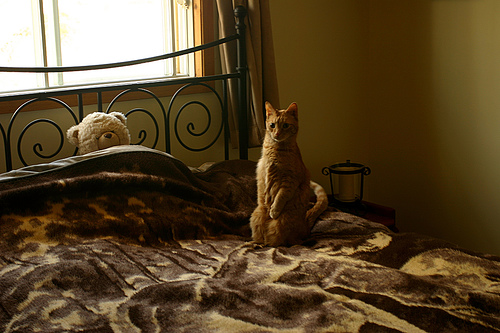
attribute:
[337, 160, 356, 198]
candle — white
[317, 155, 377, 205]
container — wire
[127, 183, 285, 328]
duvet — heavy, brown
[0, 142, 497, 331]
brown duvet — heavy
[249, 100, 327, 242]
cat — upright, sitting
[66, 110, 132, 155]
teddy bear — tucked in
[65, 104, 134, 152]
teddy bear — beige, beautiful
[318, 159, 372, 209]
lamp — bedside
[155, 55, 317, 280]
cat — orange and tan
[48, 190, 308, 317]
blanket — brown and tan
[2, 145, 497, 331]
duvet — brown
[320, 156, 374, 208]
basin — decorative